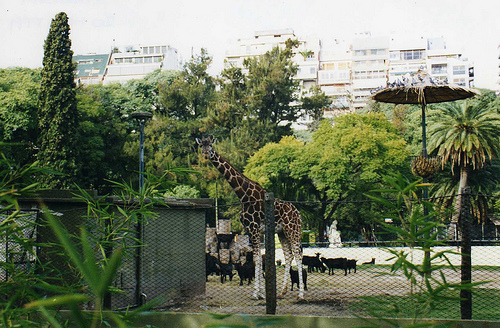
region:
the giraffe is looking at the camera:
[177, 103, 345, 309]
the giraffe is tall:
[168, 108, 319, 290]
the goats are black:
[190, 235, 375, 311]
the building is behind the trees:
[181, 20, 469, 171]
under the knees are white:
[216, 250, 311, 300]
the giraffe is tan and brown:
[210, 131, 297, 242]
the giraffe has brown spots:
[175, 120, 307, 240]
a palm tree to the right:
[410, 80, 491, 315]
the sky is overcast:
[85, 0, 465, 70]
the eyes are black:
[192, 140, 219, 150]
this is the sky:
[173, 12, 222, 34]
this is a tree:
[277, 103, 382, 189]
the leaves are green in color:
[51, 71, 71, 112]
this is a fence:
[278, 205, 372, 317]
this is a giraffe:
[198, 140, 272, 223]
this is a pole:
[134, 125, 160, 191]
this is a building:
[332, 42, 392, 90]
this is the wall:
[163, 215, 193, 260]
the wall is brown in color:
[333, 70, 372, 90]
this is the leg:
[288, 230, 301, 310]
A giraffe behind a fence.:
[190, 130, 320, 302]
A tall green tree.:
[26, 5, 108, 200]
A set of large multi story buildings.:
[210, 22, 481, 150]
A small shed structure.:
[29, 185, 228, 312]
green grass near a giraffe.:
[333, 280, 498, 325]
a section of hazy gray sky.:
[1, 3, 496, 23]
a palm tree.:
[414, 91, 495, 326]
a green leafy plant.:
[29, 198, 172, 326]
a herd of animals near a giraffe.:
[207, 230, 372, 293]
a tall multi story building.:
[100, 36, 195, 93]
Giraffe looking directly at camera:
[194, 137, 308, 304]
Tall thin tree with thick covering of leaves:
[31, 11, 83, 189]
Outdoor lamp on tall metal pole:
[125, 106, 155, 308]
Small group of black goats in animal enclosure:
[303, 252, 358, 278]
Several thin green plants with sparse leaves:
[367, 187, 470, 323]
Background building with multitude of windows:
[326, 30, 472, 102]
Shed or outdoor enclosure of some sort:
[25, 195, 207, 309]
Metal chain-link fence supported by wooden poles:
[258, 200, 493, 314]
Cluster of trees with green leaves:
[173, 63, 293, 130]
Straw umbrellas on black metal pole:
[372, 69, 474, 156]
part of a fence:
[286, 232, 328, 291]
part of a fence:
[212, 253, 254, 307]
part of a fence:
[304, 210, 335, 247]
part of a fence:
[329, 230, 366, 281]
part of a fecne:
[258, 279, 300, 321]